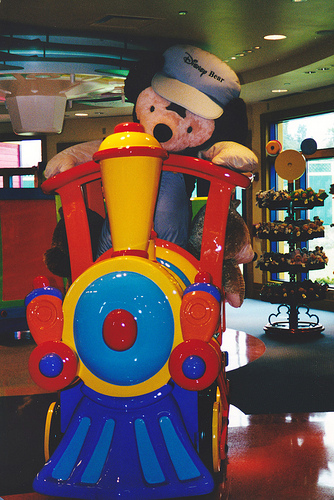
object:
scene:
[1, 3, 333, 498]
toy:
[43, 193, 106, 278]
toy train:
[26, 120, 250, 500]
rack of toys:
[252, 191, 329, 304]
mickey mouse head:
[265, 137, 318, 181]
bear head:
[227, 212, 258, 264]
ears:
[266, 139, 282, 155]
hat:
[150, 48, 246, 121]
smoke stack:
[93, 119, 169, 260]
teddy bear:
[43, 204, 110, 278]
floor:
[225, 299, 334, 499]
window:
[270, 113, 332, 290]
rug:
[229, 360, 332, 416]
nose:
[253, 251, 258, 261]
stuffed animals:
[255, 190, 263, 206]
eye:
[243, 241, 246, 244]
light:
[264, 34, 289, 42]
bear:
[190, 200, 252, 309]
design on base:
[269, 303, 319, 327]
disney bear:
[183, 51, 226, 84]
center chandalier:
[4, 92, 67, 137]